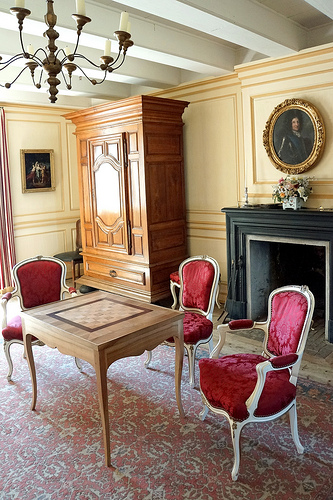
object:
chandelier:
[0, 0, 134, 104]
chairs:
[198, 285, 315, 481]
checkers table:
[19, 290, 186, 466]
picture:
[273, 108, 315, 166]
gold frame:
[282, 97, 309, 110]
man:
[275, 109, 313, 163]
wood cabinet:
[60, 95, 189, 303]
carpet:
[0, 438, 333, 500]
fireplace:
[221, 206, 333, 342]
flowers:
[272, 174, 317, 205]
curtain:
[0, 108, 16, 290]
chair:
[0, 254, 83, 381]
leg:
[289, 404, 305, 456]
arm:
[264, 353, 300, 375]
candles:
[118, 10, 130, 33]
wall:
[186, 109, 237, 205]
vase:
[283, 200, 303, 211]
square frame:
[20, 148, 56, 195]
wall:
[8, 110, 67, 140]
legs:
[93, 348, 111, 468]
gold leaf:
[232, 423, 237, 438]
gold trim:
[2, 106, 79, 256]